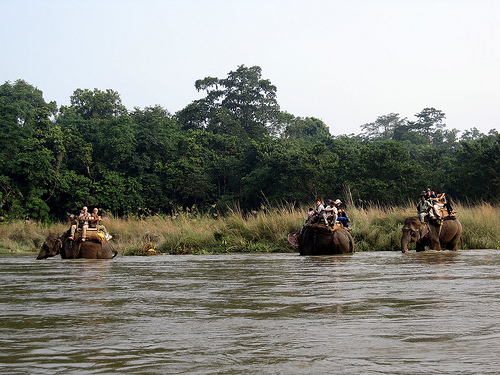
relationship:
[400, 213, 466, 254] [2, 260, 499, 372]
elephant crossing water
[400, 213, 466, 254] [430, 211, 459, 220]
elephant has seat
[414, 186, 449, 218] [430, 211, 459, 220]
people on seat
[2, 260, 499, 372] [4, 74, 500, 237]
water in jungle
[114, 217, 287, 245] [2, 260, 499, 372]
grass near water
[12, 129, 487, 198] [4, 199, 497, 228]
trees lining land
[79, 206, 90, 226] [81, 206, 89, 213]
man wearing hat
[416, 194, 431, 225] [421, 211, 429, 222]
man wearing pants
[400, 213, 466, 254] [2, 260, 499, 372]
elephant in water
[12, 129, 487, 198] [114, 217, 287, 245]
trees beyond grass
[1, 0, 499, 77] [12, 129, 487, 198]
sky above trees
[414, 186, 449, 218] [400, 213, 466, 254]
people sitting on elephant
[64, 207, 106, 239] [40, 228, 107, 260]
people sitting on elephant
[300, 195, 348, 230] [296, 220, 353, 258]
people sitting on elephant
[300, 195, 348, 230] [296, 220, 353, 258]
people riding elephant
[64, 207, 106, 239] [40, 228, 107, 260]
people on elephant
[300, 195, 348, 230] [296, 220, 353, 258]
people on elephant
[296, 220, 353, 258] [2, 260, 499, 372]
elephant crossing water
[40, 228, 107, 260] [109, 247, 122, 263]
elephant has tail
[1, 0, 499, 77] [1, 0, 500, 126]
sky has sky